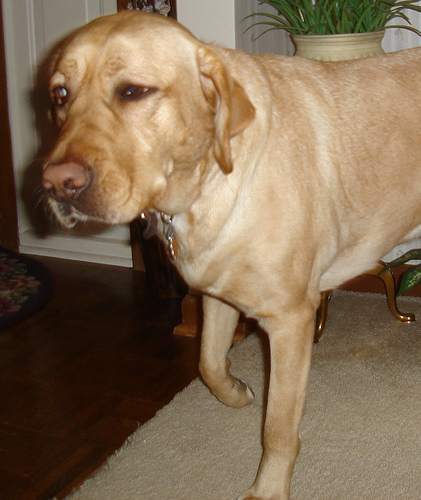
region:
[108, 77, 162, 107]
the eye of a dog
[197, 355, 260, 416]
the paw of a dog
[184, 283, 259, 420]
the leg of a dog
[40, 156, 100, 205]
the nose of a dog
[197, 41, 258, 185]
the ear of a dog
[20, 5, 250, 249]
the head of a dog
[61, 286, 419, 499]
a gray rug on the ground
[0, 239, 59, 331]
a black rug on the ground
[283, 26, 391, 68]
a white plant pot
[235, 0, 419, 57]
a green plant in the pot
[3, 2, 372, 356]
a large tan dog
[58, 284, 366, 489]
a white carpet on a hardwood floor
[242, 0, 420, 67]
a potted house plant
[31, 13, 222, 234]
a dog face with one eye squinting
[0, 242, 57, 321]
a floral rug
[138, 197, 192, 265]
a dog name tag on a collar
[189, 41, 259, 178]
a dog ear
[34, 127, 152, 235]
a brown dog nose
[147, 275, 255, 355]
wooden molding of door archway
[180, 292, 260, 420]
a dog's lifted paw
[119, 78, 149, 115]
the eye of a dog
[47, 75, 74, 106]
the eye of a dog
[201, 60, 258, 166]
the ear of a dog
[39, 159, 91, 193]
the nose of a dog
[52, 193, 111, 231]
the mouth of a dog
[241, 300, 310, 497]
the leg of a dog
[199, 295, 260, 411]
the leg of a dog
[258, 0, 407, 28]
green grass in a pot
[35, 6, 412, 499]
a brown dog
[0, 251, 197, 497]
a wooden floor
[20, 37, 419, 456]
a dog walking on carpet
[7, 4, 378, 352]
an old dog walking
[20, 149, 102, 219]
an old dog's nose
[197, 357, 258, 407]
an old dog's paw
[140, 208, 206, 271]
a dog tag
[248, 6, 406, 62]
a plant in a pot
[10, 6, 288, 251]
an old dog's face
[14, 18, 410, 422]
an old dog standing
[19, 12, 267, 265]
an old dog looking forward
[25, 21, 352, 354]
a dog standing on carpet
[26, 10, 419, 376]
A dog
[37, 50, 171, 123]
The dog has one eye partly closed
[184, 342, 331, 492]
The dog is standing on carpet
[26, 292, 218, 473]
Carpet and hardwood are in the room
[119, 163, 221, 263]
The dog has a collar and tags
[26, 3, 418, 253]
The dog is golden colored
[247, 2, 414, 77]
A plant in a vase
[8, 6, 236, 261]
The wall behind the dog is white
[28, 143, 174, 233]
The dog has white on its muzzle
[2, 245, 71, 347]
The rug has flowers on it